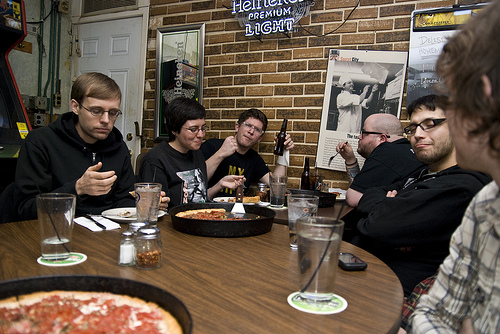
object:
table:
[0, 215, 404, 333]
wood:
[225, 263, 253, 286]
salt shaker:
[117, 232, 137, 267]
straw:
[300, 202, 345, 294]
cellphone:
[338, 253, 368, 272]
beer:
[273, 119, 287, 156]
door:
[69, 16, 141, 176]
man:
[7, 72, 170, 221]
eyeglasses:
[79, 103, 122, 118]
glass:
[296, 216, 344, 304]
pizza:
[0, 290, 181, 333]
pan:
[0, 275, 194, 334]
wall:
[139, 1, 500, 195]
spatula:
[226, 178, 248, 219]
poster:
[315, 48, 408, 173]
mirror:
[155, 23, 204, 137]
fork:
[328, 142, 348, 166]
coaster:
[286, 291, 348, 315]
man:
[336, 75, 378, 135]